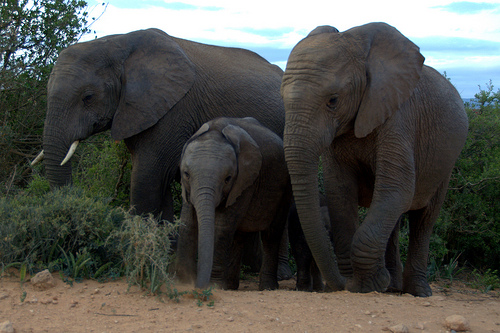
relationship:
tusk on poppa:
[29, 150, 43, 166] [29, 27, 286, 224]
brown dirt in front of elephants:
[0, 268, 498, 331] [3, 15, 480, 300]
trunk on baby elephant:
[194, 199, 216, 289] [171, 116, 310, 290]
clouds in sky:
[72, 1, 498, 48] [0, 1, 497, 103]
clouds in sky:
[422, 51, 500, 69] [1, 0, 498, 114]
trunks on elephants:
[281, 137, 353, 290] [54, 23, 452, 309]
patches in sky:
[421, 37, 496, 59] [0, 1, 497, 103]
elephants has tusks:
[31, 28, 293, 282] [16, 129, 80, 177]